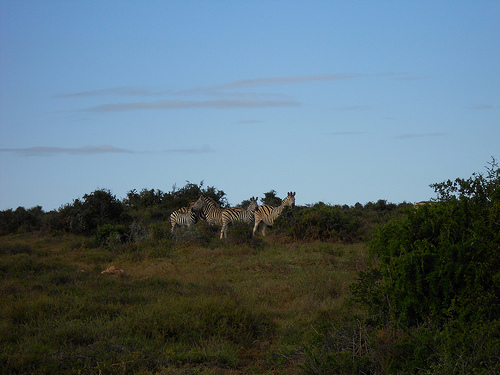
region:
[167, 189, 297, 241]
Several zebras standing together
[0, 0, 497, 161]
Small wispy clouds in a blue sky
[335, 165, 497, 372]
One large bush beside lower grasses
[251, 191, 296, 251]
One zebra standing behind a large bush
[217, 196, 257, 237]
Black and white striped zebras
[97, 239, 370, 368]
Brown and green grasses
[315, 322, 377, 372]
Small branches with no leaves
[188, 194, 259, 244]
Two zebras facing away from each other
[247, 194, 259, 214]
Black zebra nose on a striped head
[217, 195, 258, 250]
Zebra behind a short bush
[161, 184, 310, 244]
the zebras are standing together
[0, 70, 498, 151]
the clouds are long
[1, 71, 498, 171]
the clouds are faint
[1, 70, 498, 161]
the clouds are wispy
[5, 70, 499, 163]
the clouds are in the sky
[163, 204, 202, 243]
this zebra is young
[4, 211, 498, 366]
the tall grass surrounds the zebras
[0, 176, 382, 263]
the bushes surround the zebras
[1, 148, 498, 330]
the bushes are green and lush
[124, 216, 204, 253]
this bush is dry and leafless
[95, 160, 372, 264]
Zebras standing in a group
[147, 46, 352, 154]
Sky is blue with few clouds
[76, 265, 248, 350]
The grass is medium height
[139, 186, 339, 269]
Zebra's looking at the camera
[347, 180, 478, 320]
Large bush on the side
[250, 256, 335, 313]
Grass is dying in this patch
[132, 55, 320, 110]
Gray thin clouds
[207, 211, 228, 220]
The zebras are black and white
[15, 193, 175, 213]
Trees in the background of field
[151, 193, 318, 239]
Zebras are huddled together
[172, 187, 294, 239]
herd of zebras in the grass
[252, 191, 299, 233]
zebra standing in a meadow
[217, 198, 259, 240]
zebra standing in a savannah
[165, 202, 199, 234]
zebra standing in a field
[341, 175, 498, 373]
large green bush up front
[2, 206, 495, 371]
large green field with bushes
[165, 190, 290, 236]
pack of zebras standing in a field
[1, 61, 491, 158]
gray stratus clouds in the sky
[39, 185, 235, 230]
large bushes in the distance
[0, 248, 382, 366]
green shrubs on the ground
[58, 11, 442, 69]
The sky is clear and blue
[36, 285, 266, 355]
The glass is short and green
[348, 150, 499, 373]
The tree is healthy and green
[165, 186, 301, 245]
A group of zebra standing in the field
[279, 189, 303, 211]
The head of the zebra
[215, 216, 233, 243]
The back legs of the zebra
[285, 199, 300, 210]
The nose of the zebra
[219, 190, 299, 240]
The color of the zebra are black and white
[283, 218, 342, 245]
The leaves of the bush are brown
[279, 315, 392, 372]
A stack of sticks on the ground